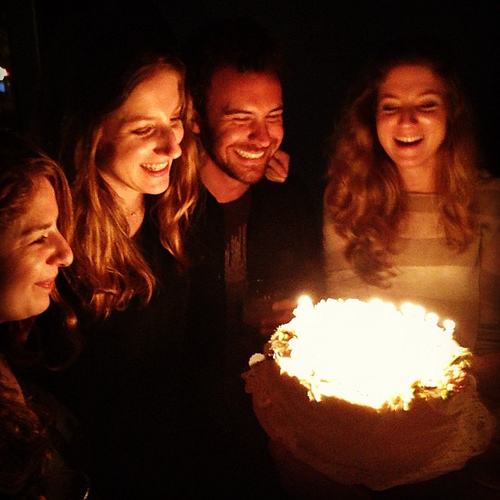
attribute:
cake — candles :
[251, 265, 471, 444]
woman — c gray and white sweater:
[319, 186, 481, 327]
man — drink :
[24, 40, 198, 403]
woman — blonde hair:
[41, 45, 211, 352]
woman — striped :
[13, 120, 73, 490]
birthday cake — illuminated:
[223, 251, 482, 444]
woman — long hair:
[329, 33, 483, 305]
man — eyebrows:
[225, 100, 249, 115]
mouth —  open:
[393, 130, 423, 151]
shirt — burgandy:
[8, 376, 111, 487]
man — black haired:
[180, 35, 289, 87]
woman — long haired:
[57, 54, 217, 288]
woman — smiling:
[378, 122, 456, 163]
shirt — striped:
[320, 191, 484, 342]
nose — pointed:
[35, 221, 95, 283]